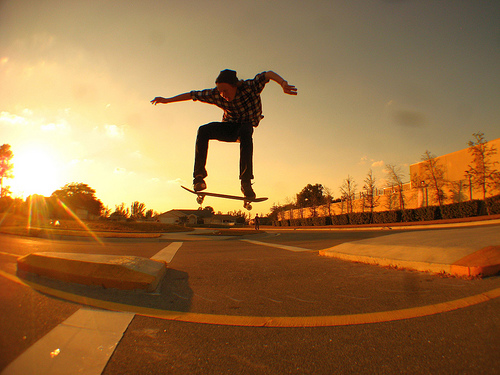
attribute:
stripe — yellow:
[105, 283, 495, 350]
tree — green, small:
[292, 200, 309, 230]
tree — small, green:
[64, 191, 106, 218]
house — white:
[148, 207, 244, 228]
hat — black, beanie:
[212, 67, 242, 90]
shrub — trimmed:
[460, 131, 499, 213]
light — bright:
[2, 146, 89, 218]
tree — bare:
[462, 130, 499, 215]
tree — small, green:
[401, 130, 458, 220]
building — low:
[274, 128, 496, 228]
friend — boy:
[251, 212, 263, 234]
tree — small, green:
[464, 132, 496, 213]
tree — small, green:
[413, 147, 459, 214]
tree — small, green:
[385, 157, 413, 220]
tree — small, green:
[357, 165, 379, 220]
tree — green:
[335, 176, 357, 226]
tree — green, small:
[466, 130, 499, 215]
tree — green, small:
[416, 148, 449, 216]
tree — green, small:
[382, 162, 406, 219]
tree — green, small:
[358, 168, 384, 225]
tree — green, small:
[338, 172, 358, 223]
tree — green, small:
[318, 182, 335, 226]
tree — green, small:
[304, 190, 319, 225]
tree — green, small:
[293, 194, 306, 226]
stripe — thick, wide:
[4, 235, 189, 371]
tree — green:
[465, 121, 498, 199]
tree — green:
[411, 144, 471, 224]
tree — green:
[378, 155, 425, 240]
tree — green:
[356, 164, 396, 234]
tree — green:
[312, 178, 359, 233]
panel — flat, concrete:
[318, 219, 499, 285]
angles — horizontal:
[319, 245, 481, 280]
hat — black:
[219, 62, 234, 78]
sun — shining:
[24, 162, 58, 196]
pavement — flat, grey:
[0, 232, 500, 373]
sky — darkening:
[0, 4, 460, 149]